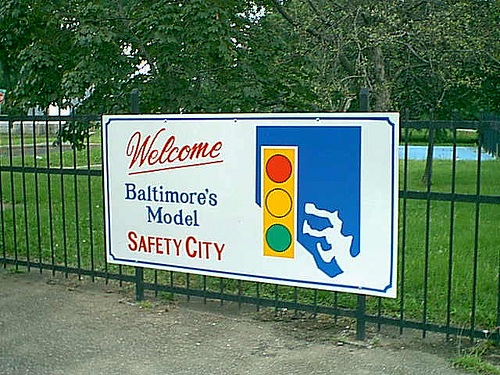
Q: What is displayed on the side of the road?
A: A sign.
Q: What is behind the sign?
A: A fence.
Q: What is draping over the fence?
A: Trees.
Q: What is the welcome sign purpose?
A: To welcome.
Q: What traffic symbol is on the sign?
A: A traffic light.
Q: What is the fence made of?
A: Metal.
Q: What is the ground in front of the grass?
A: Concrete.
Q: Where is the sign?
A: On the fence.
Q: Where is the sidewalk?
A: In front of the fence.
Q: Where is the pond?
A: Behind the trees.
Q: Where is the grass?
A: In the park.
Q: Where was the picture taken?
A: In Baltimore.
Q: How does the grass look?
A: Uncut.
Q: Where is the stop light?
A: On the sign.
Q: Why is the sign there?
A: To welcome.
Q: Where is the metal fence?
A: Between the park and the sidewalk.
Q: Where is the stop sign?
A: On fence.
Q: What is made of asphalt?
A: The ground.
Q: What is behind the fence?
A: Trees.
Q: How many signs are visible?
A: One.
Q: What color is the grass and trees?
A: Green.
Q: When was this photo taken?
A: Outside, during the daytime.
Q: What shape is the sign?
A: Rectangle.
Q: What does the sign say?
A: Welcome Baltimore's Model Safety City.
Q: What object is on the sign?
A: A traffic light.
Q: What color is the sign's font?
A: Blue and red.